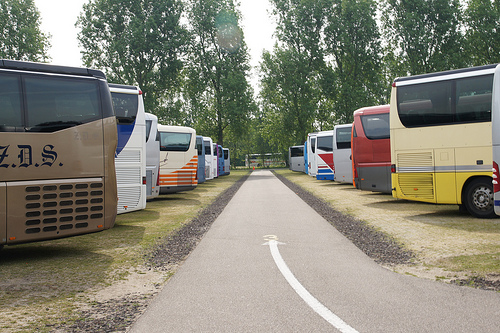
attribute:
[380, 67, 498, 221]
rv — yellow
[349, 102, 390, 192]
vehicle — red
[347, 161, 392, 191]
fender — grey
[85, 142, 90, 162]
paint — brown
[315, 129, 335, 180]
rv — white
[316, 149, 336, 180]
stripes — blue, red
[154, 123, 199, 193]
rv — white, orange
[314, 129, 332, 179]
bus — white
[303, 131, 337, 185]
rv — blue, red, white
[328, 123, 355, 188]
bus — silvery, grey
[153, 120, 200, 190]
bus — white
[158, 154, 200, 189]
stripes — orange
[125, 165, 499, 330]
road — dark gray, small, one-lane, asphalt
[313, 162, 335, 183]
paint — blue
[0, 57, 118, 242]
bus — brown, black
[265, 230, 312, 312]
line — white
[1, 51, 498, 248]
buses — parked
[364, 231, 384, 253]
rocks — gray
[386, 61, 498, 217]
bus — tan, yellow, black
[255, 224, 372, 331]
line — white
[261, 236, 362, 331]
arrow — white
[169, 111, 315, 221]
bus — blue, gray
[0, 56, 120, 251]
rv — brown, black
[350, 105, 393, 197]
bus — red, gray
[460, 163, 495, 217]
tire — black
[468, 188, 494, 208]
rim — silver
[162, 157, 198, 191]
stripes — orange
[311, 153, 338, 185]
markings — red, blue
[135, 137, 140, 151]
paint — white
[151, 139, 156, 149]
paint — gray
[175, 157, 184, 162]
paint — off white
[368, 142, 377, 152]
paint — red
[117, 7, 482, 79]
trees — tall